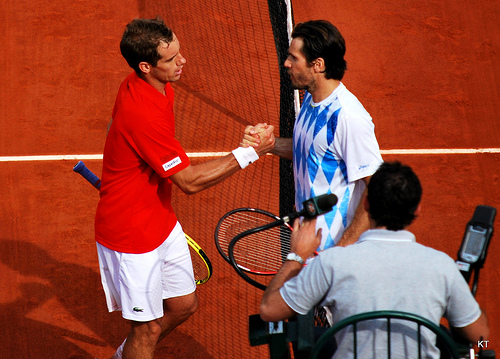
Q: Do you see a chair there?
A: Yes, there is a chair.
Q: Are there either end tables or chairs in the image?
A: Yes, there is a chair.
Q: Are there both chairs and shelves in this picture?
A: No, there is a chair but no shelves.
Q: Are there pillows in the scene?
A: No, there are no pillows.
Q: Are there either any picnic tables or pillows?
A: No, there are no pillows or picnic tables.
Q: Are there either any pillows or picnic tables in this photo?
A: No, there are no pillows or picnic tables.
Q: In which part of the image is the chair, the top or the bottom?
A: The chair is in the bottom of the image.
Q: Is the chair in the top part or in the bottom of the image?
A: The chair is in the bottom of the image.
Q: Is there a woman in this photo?
A: No, there are no women.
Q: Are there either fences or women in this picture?
A: No, there are no women or fences.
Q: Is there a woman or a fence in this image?
A: No, there are no women or fences.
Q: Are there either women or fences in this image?
A: No, there are no women or fences.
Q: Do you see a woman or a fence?
A: No, there are no women or fences.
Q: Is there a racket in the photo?
A: Yes, there is a racket.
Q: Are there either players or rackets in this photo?
A: Yes, there is a racket.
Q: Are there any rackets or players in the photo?
A: Yes, there is a racket.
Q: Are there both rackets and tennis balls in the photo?
A: No, there is a racket but no tennis balls.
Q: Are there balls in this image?
A: No, there are no balls.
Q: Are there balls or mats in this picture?
A: No, there are no balls or mats.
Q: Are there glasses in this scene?
A: No, there are no glasses.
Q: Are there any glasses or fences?
A: No, there are no glasses or fences.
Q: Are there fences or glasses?
A: No, there are no glasses or fences.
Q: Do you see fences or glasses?
A: No, there are no glasses or fences.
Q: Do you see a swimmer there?
A: No, there are no swimmers.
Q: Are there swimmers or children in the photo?
A: No, there are no swimmers or children.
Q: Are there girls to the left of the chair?
A: No, there is a man to the left of the chair.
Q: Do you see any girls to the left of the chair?
A: No, there is a man to the left of the chair.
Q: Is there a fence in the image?
A: No, there are no fences.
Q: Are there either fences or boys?
A: No, there are no fences or boys.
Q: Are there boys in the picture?
A: No, there are no boys.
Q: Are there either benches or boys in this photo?
A: No, there are no boys or benches.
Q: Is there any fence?
A: No, there are no fences.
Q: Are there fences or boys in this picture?
A: No, there are no fences or boys.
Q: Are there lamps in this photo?
A: No, there are no lamps.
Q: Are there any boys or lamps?
A: No, there are no lamps or boys.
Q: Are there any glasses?
A: No, there are no glasses.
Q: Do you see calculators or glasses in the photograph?
A: No, there are no glasses or calculators.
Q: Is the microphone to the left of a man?
A: No, the microphone is to the right of a man.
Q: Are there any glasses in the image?
A: No, there are no glasses.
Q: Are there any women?
A: No, there are no women.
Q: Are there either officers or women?
A: No, there are no women or officers.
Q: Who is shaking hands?
A: The players are shaking hands.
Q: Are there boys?
A: No, there are no boys.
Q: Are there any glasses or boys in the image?
A: No, there are no boys or glasses.